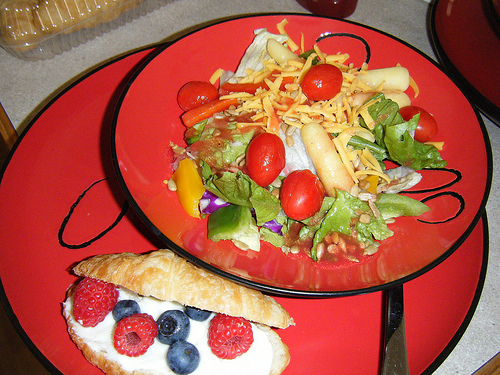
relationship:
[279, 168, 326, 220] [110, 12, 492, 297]
grape tomato in salad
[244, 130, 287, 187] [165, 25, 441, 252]
red tomato in salad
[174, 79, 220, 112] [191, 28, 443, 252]
red tomato in salad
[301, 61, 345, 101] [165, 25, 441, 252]
grape tomato in salad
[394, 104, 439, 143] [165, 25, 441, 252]
red tomato in salad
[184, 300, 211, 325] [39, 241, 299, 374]
blueberry on pastry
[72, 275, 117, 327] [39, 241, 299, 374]
raspberry on pastry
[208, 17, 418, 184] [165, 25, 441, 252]
shredded cheese on top of salad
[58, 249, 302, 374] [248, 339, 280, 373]
pastry filled with cream cheese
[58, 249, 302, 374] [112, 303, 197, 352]
pastry filled with berries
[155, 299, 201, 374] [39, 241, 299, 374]
blueberry in pastry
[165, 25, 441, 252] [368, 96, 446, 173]
salad includes lettuce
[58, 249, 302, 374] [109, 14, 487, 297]
pastry on plate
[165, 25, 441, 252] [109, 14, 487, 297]
salad on plate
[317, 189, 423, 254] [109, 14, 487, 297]
lettuce on plate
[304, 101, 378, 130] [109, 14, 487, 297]
cheese on plate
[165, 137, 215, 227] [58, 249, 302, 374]
yellow peppers on pastry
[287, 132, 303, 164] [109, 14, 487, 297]
salad dressing on plate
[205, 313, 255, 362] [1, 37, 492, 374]
blueberries on plate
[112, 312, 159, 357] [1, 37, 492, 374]
berries on plate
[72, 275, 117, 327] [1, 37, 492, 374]
raspberry on plate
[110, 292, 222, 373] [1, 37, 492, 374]
blueberries on plate